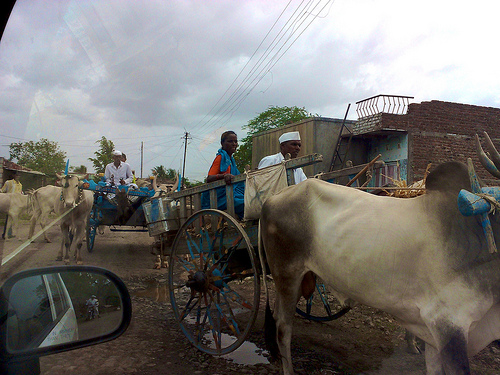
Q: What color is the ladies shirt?
A: Blue and red.